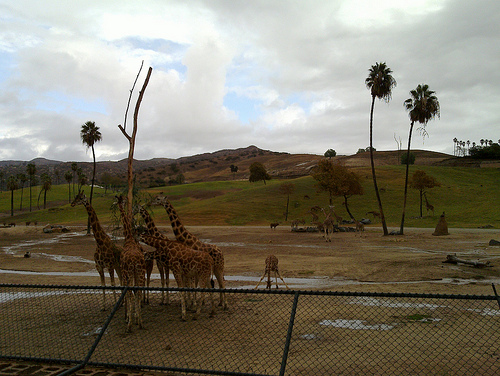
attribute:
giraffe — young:
[259, 251, 297, 311]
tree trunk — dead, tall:
[116, 68, 159, 218]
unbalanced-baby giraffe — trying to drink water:
[243, 251, 291, 291]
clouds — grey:
[0, 0, 498, 160]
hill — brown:
[173, 148, 455, 184]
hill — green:
[0, 163, 500, 224]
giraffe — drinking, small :
[31, 0, 119, 58]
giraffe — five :
[73, 174, 253, 292]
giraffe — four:
[68, 180, 255, 319]